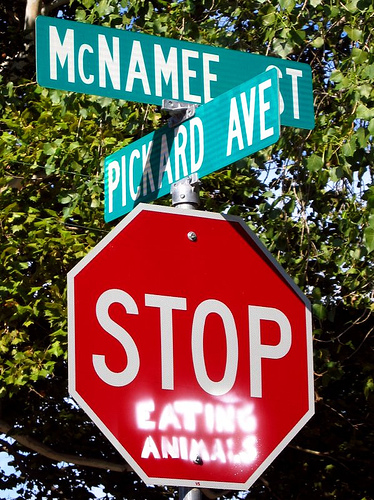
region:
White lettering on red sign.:
[124, 405, 271, 481]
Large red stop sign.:
[55, 220, 314, 479]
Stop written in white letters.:
[79, 277, 275, 391]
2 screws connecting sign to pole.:
[179, 225, 215, 475]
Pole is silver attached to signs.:
[171, 479, 195, 496]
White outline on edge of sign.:
[55, 206, 322, 491]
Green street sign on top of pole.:
[25, 14, 327, 129]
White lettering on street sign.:
[47, 20, 298, 115]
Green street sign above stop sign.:
[96, 136, 313, 184]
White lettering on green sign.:
[100, 130, 365, 178]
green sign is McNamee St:
[33, 13, 315, 131]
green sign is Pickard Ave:
[102, 67, 279, 223]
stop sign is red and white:
[66, 202, 316, 491]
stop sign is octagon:
[66, 203, 314, 489]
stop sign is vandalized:
[135, 396, 260, 463]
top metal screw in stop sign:
[187, 229, 197, 239]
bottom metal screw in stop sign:
[192, 455, 201, 462]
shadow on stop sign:
[220, 212, 311, 314]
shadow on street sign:
[132, 119, 180, 206]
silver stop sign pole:
[171, 181, 200, 498]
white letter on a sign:
[89, 286, 141, 391]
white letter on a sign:
[138, 288, 191, 393]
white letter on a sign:
[186, 296, 240, 400]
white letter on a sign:
[243, 304, 292, 400]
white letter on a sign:
[50, 24, 80, 84]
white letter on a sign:
[74, 41, 99, 86]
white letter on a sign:
[221, 90, 246, 158]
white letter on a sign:
[105, 155, 120, 216]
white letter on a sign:
[117, 149, 129, 208]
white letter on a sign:
[125, 142, 145, 205]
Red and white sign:
[93, 206, 315, 478]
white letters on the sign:
[99, 299, 293, 386]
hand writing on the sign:
[145, 393, 275, 459]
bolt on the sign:
[190, 452, 200, 469]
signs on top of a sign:
[30, 27, 316, 219]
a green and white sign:
[89, 82, 277, 230]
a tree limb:
[11, 436, 102, 461]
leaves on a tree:
[5, 93, 99, 200]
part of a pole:
[160, 487, 199, 496]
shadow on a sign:
[214, 213, 333, 324]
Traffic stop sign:
[63, 200, 314, 489]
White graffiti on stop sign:
[130, 395, 260, 466]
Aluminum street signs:
[33, 14, 315, 222]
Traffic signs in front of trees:
[2, 2, 368, 498]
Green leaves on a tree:
[1, 105, 91, 232]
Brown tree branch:
[1, 419, 133, 472]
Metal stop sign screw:
[184, 228, 198, 242]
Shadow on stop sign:
[220, 209, 313, 310]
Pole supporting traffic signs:
[160, 94, 203, 211]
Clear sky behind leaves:
[254, 155, 372, 228]